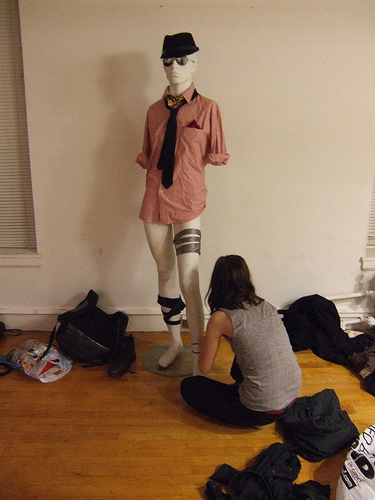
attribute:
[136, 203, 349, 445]
woman — sitting, wearing, sitted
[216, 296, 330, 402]
shirt — grey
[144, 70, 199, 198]
tie — neck, black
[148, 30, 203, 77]
glass — sun, black, manequin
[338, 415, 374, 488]
bag — plastic, paper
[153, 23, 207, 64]
hat — black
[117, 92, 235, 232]
shirt — pink, orange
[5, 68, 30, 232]
window — covered, white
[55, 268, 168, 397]
backpack — laying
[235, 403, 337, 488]
fabric — behind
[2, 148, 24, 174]
blind — closed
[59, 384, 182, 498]
floor — hardwood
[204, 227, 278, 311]
hair — brown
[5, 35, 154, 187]
wall — white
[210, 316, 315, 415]
tank — gray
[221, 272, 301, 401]
vest — grey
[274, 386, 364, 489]
clothe — black